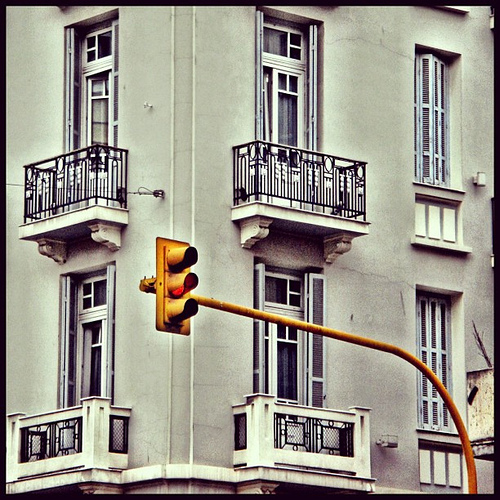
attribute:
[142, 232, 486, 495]
traffic light — yellow, over the road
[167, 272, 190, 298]
light — yellow, on, red, for emergencies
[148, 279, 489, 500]
pole — yellow, curved, big, bent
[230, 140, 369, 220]
balcony — metal, black, white framed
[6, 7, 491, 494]
building — gray, large, light colored, two story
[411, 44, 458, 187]
window — small, balcony-less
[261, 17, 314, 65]
window — open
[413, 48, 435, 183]
shutter — closed, gray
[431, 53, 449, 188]
shutter — closed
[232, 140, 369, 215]
railing — black, metal